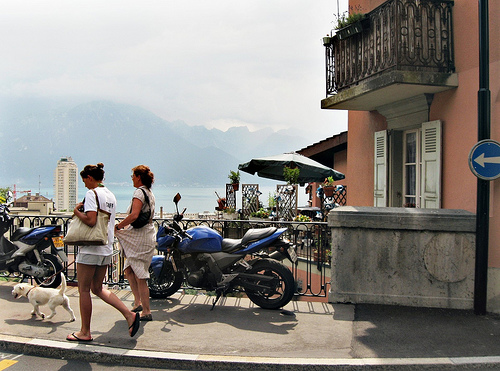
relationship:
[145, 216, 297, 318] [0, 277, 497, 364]
motorcycle on sidewalk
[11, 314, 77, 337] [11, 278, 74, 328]
shadow of dog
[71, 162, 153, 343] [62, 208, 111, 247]
lady clutching purse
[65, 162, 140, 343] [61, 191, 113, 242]
woman carrying purse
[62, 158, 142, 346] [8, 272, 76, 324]
woman walking dog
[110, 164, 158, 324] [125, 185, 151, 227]
woman carrying black bag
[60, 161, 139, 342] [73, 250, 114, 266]
person wearing shorts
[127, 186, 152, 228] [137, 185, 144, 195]
black bag on shoulder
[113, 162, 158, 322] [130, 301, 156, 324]
person wearing shoes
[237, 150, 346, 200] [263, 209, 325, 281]
umbrella over table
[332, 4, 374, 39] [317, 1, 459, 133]
planter on balcony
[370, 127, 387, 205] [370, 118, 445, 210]
shutter on window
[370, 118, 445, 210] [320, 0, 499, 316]
window on apartment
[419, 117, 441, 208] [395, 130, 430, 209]
shutter on window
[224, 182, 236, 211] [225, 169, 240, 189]
trellis with plant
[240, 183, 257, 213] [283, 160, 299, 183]
trellis with plant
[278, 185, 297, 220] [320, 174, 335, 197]
trellis with plant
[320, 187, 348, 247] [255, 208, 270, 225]
trellis with plant